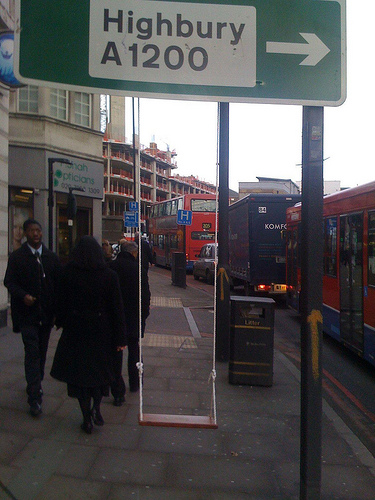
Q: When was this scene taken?
A: Yesterday.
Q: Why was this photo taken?
A: For magazine.